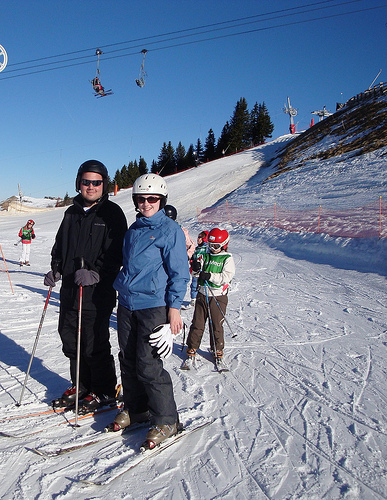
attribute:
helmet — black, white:
[75, 163, 113, 200]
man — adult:
[39, 157, 127, 412]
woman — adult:
[116, 169, 190, 449]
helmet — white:
[130, 169, 170, 202]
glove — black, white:
[141, 326, 175, 358]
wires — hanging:
[0, 2, 384, 86]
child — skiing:
[176, 223, 238, 366]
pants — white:
[19, 236, 37, 272]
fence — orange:
[196, 205, 382, 249]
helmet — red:
[202, 225, 228, 246]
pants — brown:
[185, 291, 228, 357]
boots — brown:
[107, 410, 180, 450]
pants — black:
[119, 296, 181, 430]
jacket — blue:
[118, 210, 190, 319]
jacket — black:
[45, 202, 124, 282]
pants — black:
[54, 283, 120, 401]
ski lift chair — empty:
[85, 71, 110, 100]